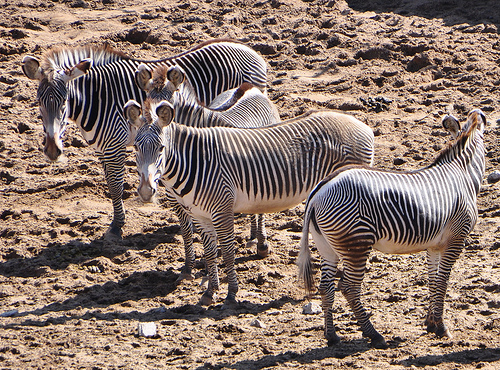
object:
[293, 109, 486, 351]
zebra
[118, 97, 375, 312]
zebra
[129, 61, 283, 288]
zebra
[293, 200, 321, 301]
tail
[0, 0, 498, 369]
dirt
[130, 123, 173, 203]
face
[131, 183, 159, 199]
nose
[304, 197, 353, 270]
back end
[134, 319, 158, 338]
rock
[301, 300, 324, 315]
rock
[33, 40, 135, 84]
mane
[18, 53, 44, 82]
ear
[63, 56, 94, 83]
ear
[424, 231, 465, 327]
legs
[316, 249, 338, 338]
legs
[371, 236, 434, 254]
belly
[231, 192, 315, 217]
belly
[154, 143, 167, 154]
eyes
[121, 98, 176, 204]
head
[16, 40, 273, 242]
zebras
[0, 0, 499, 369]
ground